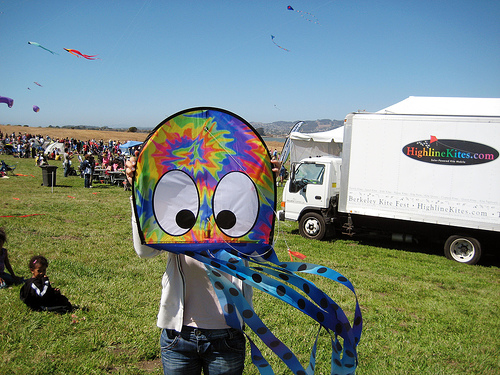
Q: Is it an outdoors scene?
A: Yes, it is outdoors.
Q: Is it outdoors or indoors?
A: It is outdoors.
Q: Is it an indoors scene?
A: No, it is outdoors.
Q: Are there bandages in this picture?
A: No, there are no bandages.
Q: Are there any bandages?
A: No, there are no bandages.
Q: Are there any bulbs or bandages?
A: No, there are no bandages or bulbs.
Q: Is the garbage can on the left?
A: Yes, the garbage can is on the left of the image.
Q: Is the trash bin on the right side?
A: No, the trash bin is on the left of the image.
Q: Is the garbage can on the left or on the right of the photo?
A: The garbage can is on the left of the image.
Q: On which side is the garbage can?
A: The garbage can is on the left of the image.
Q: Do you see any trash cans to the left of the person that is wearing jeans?
A: Yes, there is a trash can to the left of the person.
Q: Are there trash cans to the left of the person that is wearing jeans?
A: Yes, there is a trash can to the left of the person.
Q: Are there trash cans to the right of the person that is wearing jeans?
A: No, the trash can is to the left of the person.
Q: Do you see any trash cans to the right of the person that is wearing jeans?
A: No, the trash can is to the left of the person.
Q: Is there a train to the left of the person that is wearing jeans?
A: No, there is a trash can to the left of the person.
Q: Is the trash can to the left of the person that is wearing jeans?
A: Yes, the trash can is to the left of the person.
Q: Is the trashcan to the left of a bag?
A: No, the trashcan is to the left of the person.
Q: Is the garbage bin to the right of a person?
A: No, the garbage bin is to the left of a person.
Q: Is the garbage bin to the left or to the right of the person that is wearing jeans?
A: The garbage bin is to the left of the person.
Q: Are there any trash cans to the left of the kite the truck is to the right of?
A: Yes, there is a trash can to the left of the kite.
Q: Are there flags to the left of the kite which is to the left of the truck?
A: No, there is a trash can to the left of the kite.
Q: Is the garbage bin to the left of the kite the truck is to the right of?
A: Yes, the garbage bin is to the left of the kite.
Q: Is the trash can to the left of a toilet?
A: No, the trash can is to the left of the kite.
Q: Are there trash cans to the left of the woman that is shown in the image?
A: Yes, there is a trash can to the left of the woman.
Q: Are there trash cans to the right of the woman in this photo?
A: No, the trash can is to the left of the woman.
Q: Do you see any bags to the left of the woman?
A: No, there is a trash can to the left of the woman.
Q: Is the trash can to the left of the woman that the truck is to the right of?
A: Yes, the trash can is to the left of the woman.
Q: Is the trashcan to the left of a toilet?
A: No, the trashcan is to the left of the woman.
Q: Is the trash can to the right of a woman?
A: No, the trash can is to the left of a woman.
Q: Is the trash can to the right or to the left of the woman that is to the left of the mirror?
A: The trash can is to the left of the woman.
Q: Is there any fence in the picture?
A: No, there are no fences.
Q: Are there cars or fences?
A: No, there are no fences or cars.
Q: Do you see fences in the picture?
A: No, there are no fences.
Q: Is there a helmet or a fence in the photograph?
A: No, there are no fences or helmets.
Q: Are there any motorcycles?
A: No, there are no motorcycles.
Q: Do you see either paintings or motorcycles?
A: No, there are no motorcycles or paintings.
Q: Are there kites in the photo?
A: Yes, there is a kite.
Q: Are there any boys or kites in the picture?
A: Yes, there is a kite.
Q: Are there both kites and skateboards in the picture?
A: No, there is a kite but no skateboards.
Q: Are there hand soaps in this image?
A: No, there are no hand soaps.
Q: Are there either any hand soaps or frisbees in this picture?
A: No, there are no hand soaps or frisbees.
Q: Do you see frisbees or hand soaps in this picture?
A: No, there are no hand soaps or frisbees.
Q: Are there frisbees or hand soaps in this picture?
A: No, there are no hand soaps or frisbees.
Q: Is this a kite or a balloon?
A: This is a kite.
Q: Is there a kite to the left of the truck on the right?
A: Yes, there is a kite to the left of the truck.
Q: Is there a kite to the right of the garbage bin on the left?
A: Yes, there is a kite to the right of the garbage can.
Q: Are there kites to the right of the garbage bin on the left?
A: Yes, there is a kite to the right of the garbage can.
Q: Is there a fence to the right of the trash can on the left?
A: No, there is a kite to the right of the trash bin.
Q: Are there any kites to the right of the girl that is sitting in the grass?
A: Yes, there is a kite to the right of the girl.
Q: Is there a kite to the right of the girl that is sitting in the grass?
A: Yes, there is a kite to the right of the girl.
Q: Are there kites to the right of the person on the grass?
A: Yes, there is a kite to the right of the girl.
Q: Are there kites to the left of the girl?
A: No, the kite is to the right of the girl.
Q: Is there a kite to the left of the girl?
A: No, the kite is to the right of the girl.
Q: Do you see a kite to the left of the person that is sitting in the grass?
A: No, the kite is to the right of the girl.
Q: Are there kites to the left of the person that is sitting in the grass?
A: No, the kite is to the right of the girl.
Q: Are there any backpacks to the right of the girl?
A: No, there is a kite to the right of the girl.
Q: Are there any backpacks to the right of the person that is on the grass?
A: No, there is a kite to the right of the girl.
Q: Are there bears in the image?
A: No, there are no bears.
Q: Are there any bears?
A: No, there are no bears.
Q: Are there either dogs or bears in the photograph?
A: No, there are no bears or dogs.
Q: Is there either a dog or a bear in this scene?
A: No, there are no bears or dogs.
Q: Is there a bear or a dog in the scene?
A: No, there are no bears or dogs.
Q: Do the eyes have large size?
A: Yes, the eyes are large.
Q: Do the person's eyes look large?
A: Yes, the eyes are large.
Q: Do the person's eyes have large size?
A: Yes, the eyes are large.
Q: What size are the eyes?
A: The eyes are large.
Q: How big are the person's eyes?
A: The eyes are large.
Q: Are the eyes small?
A: No, the eyes are large.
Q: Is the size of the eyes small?
A: No, the eyes are large.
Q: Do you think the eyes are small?
A: No, the eyes are large.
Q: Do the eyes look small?
A: No, the eyes are large.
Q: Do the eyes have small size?
A: No, the eyes are large.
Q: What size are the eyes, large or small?
A: The eyes are large.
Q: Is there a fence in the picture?
A: No, there are no fences.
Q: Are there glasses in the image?
A: No, there are no glasses.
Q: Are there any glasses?
A: No, there are no glasses.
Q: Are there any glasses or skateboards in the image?
A: No, there are no glasses or skateboards.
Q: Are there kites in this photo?
A: Yes, there is a kite.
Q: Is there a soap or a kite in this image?
A: Yes, there is a kite.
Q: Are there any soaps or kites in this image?
A: Yes, there is a kite.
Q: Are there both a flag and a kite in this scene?
A: No, there is a kite but no flags.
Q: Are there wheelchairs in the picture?
A: No, there are no wheelchairs.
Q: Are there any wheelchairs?
A: No, there are no wheelchairs.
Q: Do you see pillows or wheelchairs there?
A: No, there are no wheelchairs or pillows.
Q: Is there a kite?
A: Yes, there is a kite.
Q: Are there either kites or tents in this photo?
A: Yes, there is a kite.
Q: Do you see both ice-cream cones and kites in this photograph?
A: No, there is a kite but no ice-cream cones.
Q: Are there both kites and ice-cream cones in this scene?
A: No, there is a kite but no ice-cream cones.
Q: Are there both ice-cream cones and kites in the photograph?
A: No, there is a kite but no ice-cream cones.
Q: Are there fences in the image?
A: No, there are no fences.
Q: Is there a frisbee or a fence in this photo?
A: No, there are no fences or frisbees.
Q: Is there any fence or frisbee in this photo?
A: No, there are no fences or frisbees.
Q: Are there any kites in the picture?
A: Yes, there is a kite.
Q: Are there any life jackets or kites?
A: Yes, there is a kite.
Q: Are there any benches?
A: No, there are no benches.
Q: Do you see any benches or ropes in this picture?
A: No, there are no benches or ropes.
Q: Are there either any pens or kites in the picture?
A: Yes, there is a kite.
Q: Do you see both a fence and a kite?
A: No, there is a kite but no fences.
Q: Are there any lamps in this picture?
A: No, there are no lamps.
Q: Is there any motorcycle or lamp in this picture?
A: No, there are no lamps or motorcycles.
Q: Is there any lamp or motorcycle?
A: No, there are no lamps or motorcycles.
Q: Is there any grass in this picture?
A: Yes, there is grass.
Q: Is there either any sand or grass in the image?
A: Yes, there is grass.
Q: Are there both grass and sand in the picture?
A: No, there is grass but no sand.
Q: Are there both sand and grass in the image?
A: No, there is grass but no sand.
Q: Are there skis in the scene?
A: No, there are no skis.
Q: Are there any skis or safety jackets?
A: No, there are no skis or safety jackets.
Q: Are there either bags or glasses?
A: No, there are no glasses or bags.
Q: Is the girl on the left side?
A: Yes, the girl is on the left of the image.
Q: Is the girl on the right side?
A: No, the girl is on the left of the image.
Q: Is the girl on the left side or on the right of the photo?
A: The girl is on the left of the image.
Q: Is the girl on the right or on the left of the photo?
A: The girl is on the left of the image.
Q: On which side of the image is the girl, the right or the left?
A: The girl is on the left of the image.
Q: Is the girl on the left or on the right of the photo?
A: The girl is on the left of the image.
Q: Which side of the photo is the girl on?
A: The girl is on the left of the image.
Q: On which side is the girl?
A: The girl is on the left of the image.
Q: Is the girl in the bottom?
A: Yes, the girl is in the bottom of the image.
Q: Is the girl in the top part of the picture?
A: No, the girl is in the bottom of the image.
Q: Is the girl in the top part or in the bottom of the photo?
A: The girl is in the bottom of the image.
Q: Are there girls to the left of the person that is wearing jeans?
A: Yes, there is a girl to the left of the person.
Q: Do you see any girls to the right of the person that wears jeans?
A: No, the girl is to the left of the person.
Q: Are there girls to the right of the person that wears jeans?
A: No, the girl is to the left of the person.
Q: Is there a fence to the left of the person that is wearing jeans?
A: No, there is a girl to the left of the person.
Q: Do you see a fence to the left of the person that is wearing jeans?
A: No, there is a girl to the left of the person.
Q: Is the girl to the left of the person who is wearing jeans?
A: Yes, the girl is to the left of the person.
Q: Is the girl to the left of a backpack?
A: No, the girl is to the left of the person.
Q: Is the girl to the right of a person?
A: No, the girl is to the left of a person.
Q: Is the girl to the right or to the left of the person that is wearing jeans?
A: The girl is to the left of the person.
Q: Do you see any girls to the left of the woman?
A: Yes, there is a girl to the left of the woman.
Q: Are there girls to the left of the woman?
A: Yes, there is a girl to the left of the woman.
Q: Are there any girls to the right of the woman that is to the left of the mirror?
A: No, the girl is to the left of the woman.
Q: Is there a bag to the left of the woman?
A: No, there is a girl to the left of the woman.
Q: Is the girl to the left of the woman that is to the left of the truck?
A: Yes, the girl is to the left of the woman.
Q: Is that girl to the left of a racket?
A: No, the girl is to the left of the woman.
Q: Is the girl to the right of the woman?
A: No, the girl is to the left of the woman.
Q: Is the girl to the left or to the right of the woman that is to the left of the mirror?
A: The girl is to the left of the woman.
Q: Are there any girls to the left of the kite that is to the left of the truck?
A: Yes, there is a girl to the left of the kite.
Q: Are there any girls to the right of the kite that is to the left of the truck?
A: No, the girl is to the left of the kite.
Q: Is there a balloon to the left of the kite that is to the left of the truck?
A: No, there is a girl to the left of the kite.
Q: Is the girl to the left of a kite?
A: Yes, the girl is to the left of a kite.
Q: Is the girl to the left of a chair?
A: No, the girl is to the left of a kite.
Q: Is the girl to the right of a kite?
A: No, the girl is to the left of a kite.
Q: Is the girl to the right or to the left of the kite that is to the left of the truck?
A: The girl is to the left of the kite.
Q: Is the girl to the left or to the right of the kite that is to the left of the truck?
A: The girl is to the left of the kite.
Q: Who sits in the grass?
A: The girl sits in the grass.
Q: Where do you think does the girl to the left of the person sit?
A: The girl sits in the grass.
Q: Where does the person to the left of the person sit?
A: The girl sits in the grass.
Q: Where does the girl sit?
A: The girl sits in the grass.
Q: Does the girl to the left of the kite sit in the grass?
A: Yes, the girl sits in the grass.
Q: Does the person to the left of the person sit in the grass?
A: Yes, the girl sits in the grass.